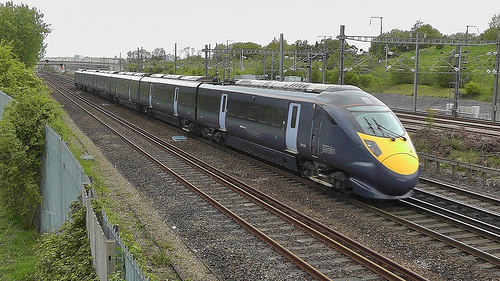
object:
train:
[76, 66, 419, 203]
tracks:
[40, 66, 499, 280]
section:
[283, 86, 417, 200]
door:
[284, 103, 306, 159]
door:
[217, 93, 232, 130]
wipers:
[366, 116, 403, 144]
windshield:
[346, 105, 414, 144]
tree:
[2, 2, 47, 77]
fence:
[1, 87, 152, 279]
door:
[172, 86, 179, 120]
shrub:
[1, 97, 45, 224]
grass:
[74, 145, 120, 189]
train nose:
[346, 113, 421, 193]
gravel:
[112, 201, 223, 278]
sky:
[56, 1, 320, 33]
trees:
[0, 0, 59, 110]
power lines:
[73, 22, 495, 117]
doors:
[146, 80, 152, 110]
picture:
[0, 1, 499, 278]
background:
[2, 4, 499, 115]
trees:
[125, 23, 498, 72]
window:
[271, 107, 288, 131]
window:
[225, 100, 237, 118]